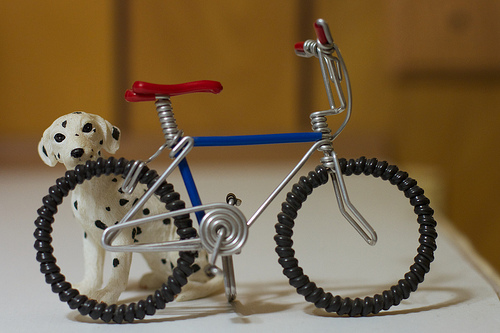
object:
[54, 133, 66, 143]
eyes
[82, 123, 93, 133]
eye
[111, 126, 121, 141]
spot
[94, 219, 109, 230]
spot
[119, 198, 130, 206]
spot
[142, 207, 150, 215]
spot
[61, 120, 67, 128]
spot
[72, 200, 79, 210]
spot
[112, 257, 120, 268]
spot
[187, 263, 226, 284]
pedal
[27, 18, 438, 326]
bicycle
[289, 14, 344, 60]
handle bars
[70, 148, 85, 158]
dog nose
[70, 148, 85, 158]
black nose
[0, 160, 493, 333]
table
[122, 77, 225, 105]
seat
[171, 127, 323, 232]
blue body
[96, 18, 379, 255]
frame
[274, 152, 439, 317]
tire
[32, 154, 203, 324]
tire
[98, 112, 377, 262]
frame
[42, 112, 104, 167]
face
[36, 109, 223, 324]
dog